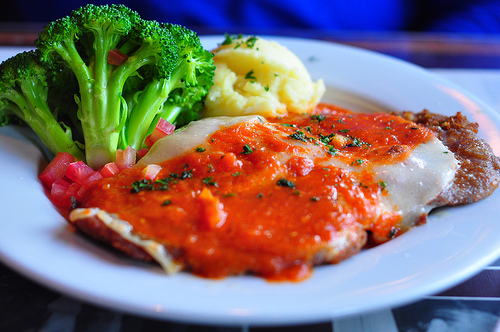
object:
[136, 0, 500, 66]
person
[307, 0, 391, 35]
blue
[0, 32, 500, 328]
plate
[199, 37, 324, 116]
potatoes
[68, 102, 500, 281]
pasta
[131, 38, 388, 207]
seasoning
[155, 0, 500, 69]
shirt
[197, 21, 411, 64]
edge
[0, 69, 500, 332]
table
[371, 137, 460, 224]
cheese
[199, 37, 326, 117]
mashed potato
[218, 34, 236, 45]
parsley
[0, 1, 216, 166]
broccoli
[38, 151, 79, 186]
radish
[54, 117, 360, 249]
dressing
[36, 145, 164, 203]
tomatoes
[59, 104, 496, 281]
meat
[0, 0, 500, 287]
food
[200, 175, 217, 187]
herb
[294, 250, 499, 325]
edge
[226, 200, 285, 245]
pasta sauce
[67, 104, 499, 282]
chicken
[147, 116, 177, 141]
onions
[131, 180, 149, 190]
chives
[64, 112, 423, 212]
toppings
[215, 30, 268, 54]
toppings